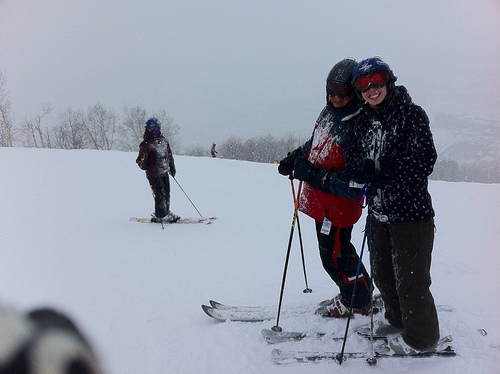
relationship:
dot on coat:
[356, 110, 378, 127] [353, 100, 439, 224]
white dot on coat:
[419, 212, 424, 219] [336, 83, 441, 224]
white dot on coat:
[406, 216, 418, 223] [336, 83, 441, 224]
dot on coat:
[394, 205, 408, 225] [329, 93, 435, 225]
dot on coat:
[407, 171, 422, 182] [331, 100, 443, 228]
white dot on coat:
[393, 182, 405, 194] [350, 84, 440, 224]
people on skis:
[281, 57, 454, 357] [202, 280, 347, 362]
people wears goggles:
[270, 44, 453, 358] [349, 72, 395, 94]